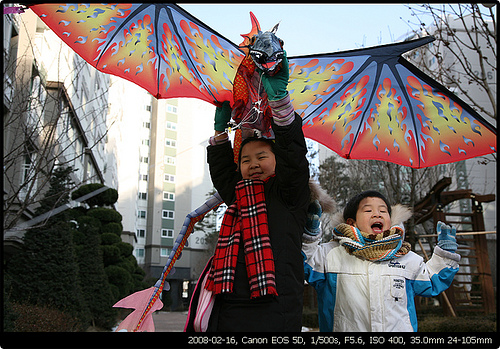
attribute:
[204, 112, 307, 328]
coat — black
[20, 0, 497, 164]
kite — colorful, dragon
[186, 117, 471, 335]
children — standing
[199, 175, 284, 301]
scarf — plaid, red, white, black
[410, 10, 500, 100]
tree branches — bare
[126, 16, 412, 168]
wings — open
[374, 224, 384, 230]
mouth — open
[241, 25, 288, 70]
head — grey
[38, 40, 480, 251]
scene — daytime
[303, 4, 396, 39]
sky — blue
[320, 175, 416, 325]
kid — asian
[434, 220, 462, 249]
glove — blue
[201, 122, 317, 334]
girl — smiling